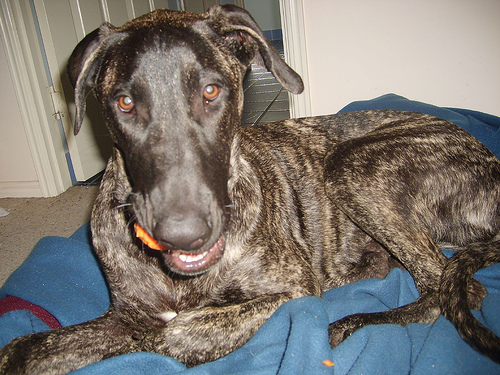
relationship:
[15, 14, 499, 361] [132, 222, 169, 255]
dog eats bread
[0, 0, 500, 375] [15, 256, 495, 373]
dog on blanket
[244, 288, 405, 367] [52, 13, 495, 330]
blanket under dog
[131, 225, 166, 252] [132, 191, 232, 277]
object in mouth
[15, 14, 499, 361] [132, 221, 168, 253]
dog with ball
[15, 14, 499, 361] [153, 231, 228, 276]
dog in mouth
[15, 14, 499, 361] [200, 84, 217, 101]
dog with eye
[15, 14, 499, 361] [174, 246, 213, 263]
dog showing teeth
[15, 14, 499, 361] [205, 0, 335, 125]
dog has ear